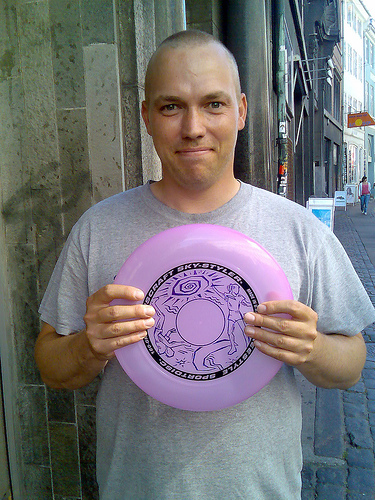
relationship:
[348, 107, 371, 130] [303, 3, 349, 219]
sign extends from building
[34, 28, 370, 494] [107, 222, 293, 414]
man holding frisbee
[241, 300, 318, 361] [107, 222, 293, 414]
hand holding frisbee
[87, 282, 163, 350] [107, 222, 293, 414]
hand holding frisbee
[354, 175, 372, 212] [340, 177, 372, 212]
woman in jacket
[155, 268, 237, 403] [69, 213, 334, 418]
drawing in frisbee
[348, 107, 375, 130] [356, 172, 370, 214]
sign by woman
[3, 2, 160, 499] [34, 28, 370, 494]
wall left of man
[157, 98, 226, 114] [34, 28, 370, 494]
eyes of man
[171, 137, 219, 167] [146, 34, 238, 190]
smile on h face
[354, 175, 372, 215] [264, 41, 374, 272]
woman in background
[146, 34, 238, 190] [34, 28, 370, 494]
face on man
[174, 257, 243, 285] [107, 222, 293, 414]
sky-styler on frisbee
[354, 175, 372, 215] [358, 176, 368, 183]
woman has dark hair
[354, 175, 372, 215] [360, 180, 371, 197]
woman wears pink shirt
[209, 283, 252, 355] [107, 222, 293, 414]
woman on frisbee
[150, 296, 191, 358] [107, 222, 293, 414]
woman on frisbee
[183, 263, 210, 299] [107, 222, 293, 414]
sun on frisbee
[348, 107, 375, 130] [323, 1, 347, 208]
sign on building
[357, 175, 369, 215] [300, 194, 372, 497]
person on street